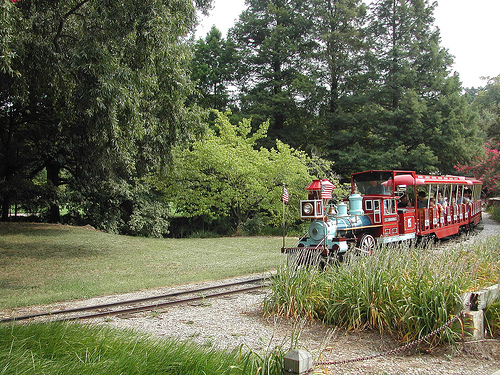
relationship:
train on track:
[278, 160, 492, 256] [280, 177, 478, 237]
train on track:
[275, 167, 485, 267] [2, 224, 498, 329]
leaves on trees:
[3, 1, 498, 237] [2, 1, 498, 242]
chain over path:
[295, 294, 466, 374] [240, 319, 497, 372]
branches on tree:
[43, 61, 163, 189] [2, 2, 220, 234]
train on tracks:
[278, 160, 492, 280] [4, 270, 298, 335]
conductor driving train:
[358, 174, 388, 198] [264, 153, 495, 301]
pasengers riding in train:
[409, 186, 431, 211] [278, 160, 492, 256]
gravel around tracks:
[118, 284, 265, 338] [0, 272, 277, 335]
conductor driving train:
[358, 174, 388, 198] [288, 166, 484, 271]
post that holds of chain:
[282, 345, 315, 371] [300, 311, 462, 367]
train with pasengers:
[275, 167, 485, 267] [409, 186, 476, 211]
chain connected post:
[300, 311, 462, 367] [458, 285, 498, 335]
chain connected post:
[300, 311, 462, 367] [277, 344, 309, 374]